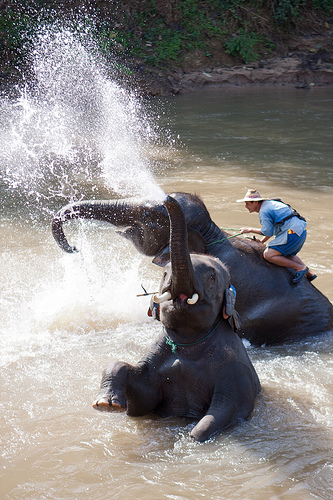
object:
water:
[1, 0, 195, 315]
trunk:
[51, 197, 143, 252]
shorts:
[268, 229, 307, 257]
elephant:
[115, 192, 309, 351]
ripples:
[212, 160, 328, 191]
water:
[0, 83, 333, 499]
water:
[0, 255, 333, 499]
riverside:
[0, 56, 333, 100]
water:
[0, 146, 332, 498]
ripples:
[25, 387, 330, 494]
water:
[0, 11, 325, 490]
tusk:
[153, 292, 172, 304]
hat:
[235, 189, 269, 203]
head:
[245, 193, 263, 213]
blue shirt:
[258, 199, 307, 246]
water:
[63, 86, 248, 196]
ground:
[200, 40, 227, 57]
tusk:
[187, 293, 198, 304]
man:
[236, 189, 318, 284]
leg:
[92, 351, 161, 413]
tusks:
[152, 292, 198, 305]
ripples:
[273, 389, 321, 424]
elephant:
[92, 195, 262, 443]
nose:
[162, 194, 204, 300]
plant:
[128, 0, 248, 52]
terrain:
[0, 0, 333, 103]